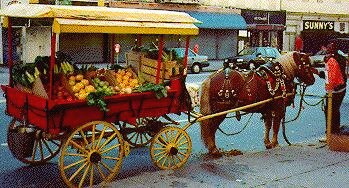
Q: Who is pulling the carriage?
A: Horse.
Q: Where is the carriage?
A: Behind the horse.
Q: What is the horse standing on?
A: Waste.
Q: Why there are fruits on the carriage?
A: For sale.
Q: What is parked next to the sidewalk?
A: Horse and carriage.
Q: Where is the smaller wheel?
A: Front wheel.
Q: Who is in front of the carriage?
A: Horse.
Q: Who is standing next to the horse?
A: Guy.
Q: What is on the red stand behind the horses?
A: Fruit.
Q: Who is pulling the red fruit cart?
A: A horse.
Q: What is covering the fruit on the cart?
A: A yellow roof.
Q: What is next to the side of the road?
A: A horse pulling a wagon with fruits and vegetables.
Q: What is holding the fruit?
A: A red cart.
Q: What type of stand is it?
A: A fruit stand.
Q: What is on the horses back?
A: A saddle.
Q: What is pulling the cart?
A: Horse.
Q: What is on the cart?
A: Produce.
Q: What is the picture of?
A: Fruit wagon.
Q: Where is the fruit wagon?
A: On the street.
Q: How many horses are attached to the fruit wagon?
A: One.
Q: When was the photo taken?
A: Daytime.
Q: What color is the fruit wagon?
A: Red and yellow.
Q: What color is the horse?
A: Brown.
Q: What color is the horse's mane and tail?
A: Tan.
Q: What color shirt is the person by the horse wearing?
A: Red.